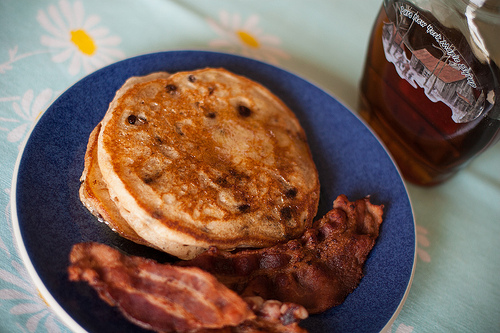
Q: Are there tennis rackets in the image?
A: No, there are no tennis rackets.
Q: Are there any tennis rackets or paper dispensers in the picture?
A: No, there are no tennis rackets or paper dispensers.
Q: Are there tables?
A: Yes, there is a table.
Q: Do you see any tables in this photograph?
A: Yes, there is a table.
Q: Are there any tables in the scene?
A: Yes, there is a table.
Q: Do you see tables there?
A: Yes, there is a table.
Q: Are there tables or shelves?
A: Yes, there is a table.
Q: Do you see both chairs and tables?
A: No, there is a table but no chairs.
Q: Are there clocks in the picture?
A: No, there are no clocks.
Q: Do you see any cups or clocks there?
A: No, there are no clocks or cups.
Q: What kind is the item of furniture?
A: The piece of furniture is a table.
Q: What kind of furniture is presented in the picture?
A: The furniture is a table.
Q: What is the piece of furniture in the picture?
A: The piece of furniture is a table.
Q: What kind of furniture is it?
A: The piece of furniture is a table.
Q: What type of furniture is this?
A: This is a table.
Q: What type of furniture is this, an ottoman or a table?
A: This is a table.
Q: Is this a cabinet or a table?
A: This is a table.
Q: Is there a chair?
A: No, there are no chairs.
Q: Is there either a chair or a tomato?
A: No, there are no chairs or tomatoes.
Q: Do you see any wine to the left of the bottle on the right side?
A: No, there is breakfast to the left of the bottle.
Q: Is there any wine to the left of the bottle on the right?
A: No, there is breakfast to the left of the bottle.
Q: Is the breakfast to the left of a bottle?
A: Yes, the breakfast is to the left of a bottle.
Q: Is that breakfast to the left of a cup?
A: No, the breakfast is to the left of a bottle.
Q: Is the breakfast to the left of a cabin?
A: Yes, the breakfast is to the left of a cabin.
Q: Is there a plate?
A: Yes, there is a plate.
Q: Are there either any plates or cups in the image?
A: Yes, there is a plate.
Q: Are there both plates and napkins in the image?
A: No, there is a plate but no napkins.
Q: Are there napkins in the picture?
A: No, there are no napkins.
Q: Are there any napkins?
A: No, there are no napkins.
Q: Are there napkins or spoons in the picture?
A: No, there are no napkins or spoons.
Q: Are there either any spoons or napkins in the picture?
A: No, there are no napkins or spoons.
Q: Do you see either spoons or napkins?
A: No, there are no napkins or spoons.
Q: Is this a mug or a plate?
A: This is a plate.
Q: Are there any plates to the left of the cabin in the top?
A: Yes, there is a plate to the left of the cabin.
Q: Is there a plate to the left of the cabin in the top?
A: Yes, there is a plate to the left of the cabin.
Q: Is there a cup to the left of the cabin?
A: No, there is a plate to the left of the cabin.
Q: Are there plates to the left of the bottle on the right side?
A: Yes, there is a plate to the left of the bottle.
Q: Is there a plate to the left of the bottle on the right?
A: Yes, there is a plate to the left of the bottle.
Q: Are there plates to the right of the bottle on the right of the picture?
A: No, the plate is to the left of the bottle.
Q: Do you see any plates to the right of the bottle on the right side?
A: No, the plate is to the left of the bottle.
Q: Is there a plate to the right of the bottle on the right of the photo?
A: No, the plate is to the left of the bottle.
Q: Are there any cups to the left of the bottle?
A: No, there is a plate to the left of the bottle.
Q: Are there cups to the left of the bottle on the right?
A: No, there is a plate to the left of the bottle.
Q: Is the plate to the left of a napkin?
A: No, the plate is to the left of the bottle.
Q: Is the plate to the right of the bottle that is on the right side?
A: No, the plate is to the left of the bottle.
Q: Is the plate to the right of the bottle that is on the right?
A: No, the plate is to the left of the bottle.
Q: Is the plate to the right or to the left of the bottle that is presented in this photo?
A: The plate is to the left of the bottle.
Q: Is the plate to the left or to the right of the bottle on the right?
A: The plate is to the left of the bottle.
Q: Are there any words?
A: Yes, there are words.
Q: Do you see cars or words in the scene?
A: Yes, there are words.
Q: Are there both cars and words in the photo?
A: No, there are words but no cars.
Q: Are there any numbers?
A: No, there are no numbers.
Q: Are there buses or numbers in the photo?
A: No, there are no numbers or buses.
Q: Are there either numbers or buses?
A: No, there are no numbers or buses.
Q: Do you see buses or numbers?
A: No, there are no numbers or buses.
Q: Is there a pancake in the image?
A: Yes, there is a pancake.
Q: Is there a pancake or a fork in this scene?
A: Yes, there is a pancake.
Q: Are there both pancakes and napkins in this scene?
A: No, there is a pancake but no napkins.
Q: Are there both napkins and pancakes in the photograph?
A: No, there is a pancake but no napkins.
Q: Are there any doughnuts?
A: No, there are no doughnuts.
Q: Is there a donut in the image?
A: No, there are no donuts.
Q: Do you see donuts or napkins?
A: No, there are no donuts or napkins.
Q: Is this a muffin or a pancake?
A: This is a pancake.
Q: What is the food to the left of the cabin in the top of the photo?
A: The food is a pancake.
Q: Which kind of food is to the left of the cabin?
A: The food is a pancake.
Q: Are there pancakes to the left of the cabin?
A: Yes, there is a pancake to the left of the cabin.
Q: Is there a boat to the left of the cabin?
A: No, there is a pancake to the left of the cabin.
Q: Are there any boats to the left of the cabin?
A: No, there is a pancake to the left of the cabin.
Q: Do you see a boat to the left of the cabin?
A: No, there is a pancake to the left of the cabin.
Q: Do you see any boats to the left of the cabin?
A: No, there is a pancake to the left of the cabin.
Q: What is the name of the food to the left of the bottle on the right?
A: The food is a pancake.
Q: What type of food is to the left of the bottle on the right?
A: The food is a pancake.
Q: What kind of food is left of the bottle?
A: The food is a pancake.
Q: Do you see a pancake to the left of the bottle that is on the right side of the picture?
A: Yes, there is a pancake to the left of the bottle.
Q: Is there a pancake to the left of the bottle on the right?
A: Yes, there is a pancake to the left of the bottle.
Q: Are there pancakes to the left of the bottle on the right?
A: Yes, there is a pancake to the left of the bottle.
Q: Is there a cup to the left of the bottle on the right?
A: No, there is a pancake to the left of the bottle.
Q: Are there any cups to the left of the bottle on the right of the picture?
A: No, there is a pancake to the left of the bottle.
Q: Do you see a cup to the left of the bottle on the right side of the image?
A: No, there is a pancake to the left of the bottle.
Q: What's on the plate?
A: The pancake is on the plate.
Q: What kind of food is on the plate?
A: The food is a pancake.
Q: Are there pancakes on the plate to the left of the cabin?
A: Yes, there is a pancake on the plate.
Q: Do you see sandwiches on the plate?
A: No, there is a pancake on the plate.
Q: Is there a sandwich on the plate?
A: No, there is a pancake on the plate.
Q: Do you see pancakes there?
A: Yes, there are pancakes.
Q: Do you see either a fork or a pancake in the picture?
A: Yes, there are pancakes.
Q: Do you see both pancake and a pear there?
A: No, there are pancakes but no pears.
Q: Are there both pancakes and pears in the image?
A: No, there are pancakes but no pears.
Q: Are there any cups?
A: No, there are no cups.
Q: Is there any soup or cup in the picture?
A: No, there are no cups or soup.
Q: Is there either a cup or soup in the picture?
A: No, there are no cups or soup.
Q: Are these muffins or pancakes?
A: These are pancakes.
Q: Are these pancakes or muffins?
A: These are pancakes.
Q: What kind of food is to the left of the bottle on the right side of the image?
A: The food is pancakes.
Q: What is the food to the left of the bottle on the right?
A: The food is pancakes.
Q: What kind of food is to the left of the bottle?
A: The food is pancakes.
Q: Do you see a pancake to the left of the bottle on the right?
A: Yes, there are pancakes to the left of the bottle.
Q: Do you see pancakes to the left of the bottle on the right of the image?
A: Yes, there are pancakes to the left of the bottle.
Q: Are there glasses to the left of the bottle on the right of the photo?
A: No, there are pancakes to the left of the bottle.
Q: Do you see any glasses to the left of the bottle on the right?
A: No, there are pancakes to the left of the bottle.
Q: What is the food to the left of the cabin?
A: The food is pancakes.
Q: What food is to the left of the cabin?
A: The food is pancakes.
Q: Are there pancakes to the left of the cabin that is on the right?
A: Yes, there are pancakes to the left of the cabin.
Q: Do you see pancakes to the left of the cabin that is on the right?
A: Yes, there are pancakes to the left of the cabin.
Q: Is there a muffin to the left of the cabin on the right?
A: No, there are pancakes to the left of the cabin.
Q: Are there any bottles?
A: Yes, there is a bottle.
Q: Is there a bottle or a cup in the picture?
A: Yes, there is a bottle.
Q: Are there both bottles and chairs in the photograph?
A: No, there is a bottle but no chairs.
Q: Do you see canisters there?
A: No, there are no canisters.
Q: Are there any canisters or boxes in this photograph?
A: No, there are no canisters or boxes.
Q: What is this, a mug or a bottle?
A: This is a bottle.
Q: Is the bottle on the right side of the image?
A: Yes, the bottle is on the right of the image.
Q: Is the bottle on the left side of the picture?
A: No, the bottle is on the right of the image.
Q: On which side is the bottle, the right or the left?
A: The bottle is on the right of the image.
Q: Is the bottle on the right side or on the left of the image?
A: The bottle is on the right of the image.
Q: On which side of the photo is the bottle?
A: The bottle is on the right of the image.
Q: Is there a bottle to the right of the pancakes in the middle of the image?
A: Yes, there is a bottle to the right of the pancakes.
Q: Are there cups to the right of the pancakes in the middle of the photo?
A: No, there is a bottle to the right of the pancakes.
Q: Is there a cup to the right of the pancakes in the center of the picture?
A: No, there is a bottle to the right of the pancakes.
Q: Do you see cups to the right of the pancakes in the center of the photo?
A: No, there is a bottle to the right of the pancakes.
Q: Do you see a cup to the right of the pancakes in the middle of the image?
A: No, there is a bottle to the right of the pancakes.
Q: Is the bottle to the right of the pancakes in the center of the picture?
A: Yes, the bottle is to the right of the pancakes.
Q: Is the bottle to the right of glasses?
A: No, the bottle is to the right of the pancakes.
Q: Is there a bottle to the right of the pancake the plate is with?
A: Yes, there is a bottle to the right of the pancake.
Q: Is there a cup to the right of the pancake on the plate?
A: No, there is a bottle to the right of the pancake.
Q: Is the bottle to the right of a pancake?
A: Yes, the bottle is to the right of a pancake.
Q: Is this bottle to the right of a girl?
A: No, the bottle is to the right of a pancake.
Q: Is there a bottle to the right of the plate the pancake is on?
A: Yes, there is a bottle to the right of the plate.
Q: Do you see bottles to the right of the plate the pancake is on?
A: Yes, there is a bottle to the right of the plate.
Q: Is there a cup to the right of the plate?
A: No, there is a bottle to the right of the plate.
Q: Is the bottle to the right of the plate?
A: Yes, the bottle is to the right of the plate.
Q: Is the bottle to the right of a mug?
A: No, the bottle is to the right of the plate.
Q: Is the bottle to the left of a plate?
A: No, the bottle is to the right of a plate.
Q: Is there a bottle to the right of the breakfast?
A: Yes, there is a bottle to the right of the breakfast.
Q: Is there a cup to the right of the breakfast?
A: No, there is a bottle to the right of the breakfast.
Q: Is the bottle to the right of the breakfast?
A: Yes, the bottle is to the right of the breakfast.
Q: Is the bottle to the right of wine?
A: No, the bottle is to the right of the breakfast.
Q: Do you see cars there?
A: No, there are no cars.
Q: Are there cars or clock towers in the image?
A: No, there are no cars or clock towers.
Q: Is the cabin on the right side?
A: Yes, the cabin is on the right of the image.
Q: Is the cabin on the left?
A: No, the cabin is on the right of the image.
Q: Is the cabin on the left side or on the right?
A: The cabin is on the right of the image.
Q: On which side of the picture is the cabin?
A: The cabin is on the right of the image.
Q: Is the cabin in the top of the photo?
A: Yes, the cabin is in the top of the image.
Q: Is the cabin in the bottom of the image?
A: No, the cabin is in the top of the image.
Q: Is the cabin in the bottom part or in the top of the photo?
A: The cabin is in the top of the image.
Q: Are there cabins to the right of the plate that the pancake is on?
A: Yes, there is a cabin to the right of the plate.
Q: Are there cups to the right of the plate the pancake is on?
A: No, there is a cabin to the right of the plate.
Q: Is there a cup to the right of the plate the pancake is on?
A: No, there is a cabin to the right of the plate.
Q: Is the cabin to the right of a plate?
A: Yes, the cabin is to the right of a plate.